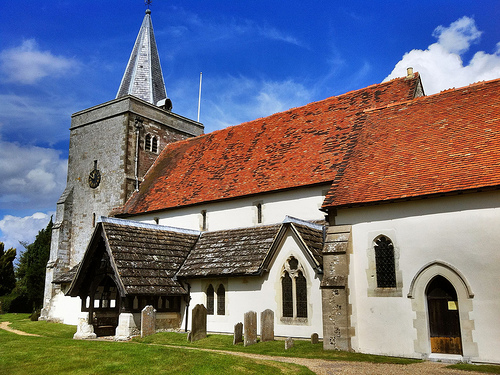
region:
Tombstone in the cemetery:
[138, 303, 158, 342]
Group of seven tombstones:
[140, 300, 324, 356]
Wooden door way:
[411, 260, 463, 359]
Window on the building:
[365, 230, 401, 297]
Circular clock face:
[84, 161, 106, 195]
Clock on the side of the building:
[85, 163, 103, 190]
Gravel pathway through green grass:
[0, 305, 480, 374]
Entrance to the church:
[82, 255, 126, 343]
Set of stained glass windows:
[277, 251, 310, 326]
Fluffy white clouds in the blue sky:
[348, 4, 498, 102]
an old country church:
[40, 5, 497, 374]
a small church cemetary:
[133, 290, 325, 353]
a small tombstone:
[308, 332, 318, 346]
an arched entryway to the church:
[411, 257, 481, 362]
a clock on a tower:
[84, 163, 105, 191]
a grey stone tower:
[62, 106, 213, 315]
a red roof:
[113, 67, 498, 215]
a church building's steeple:
[112, 7, 177, 119]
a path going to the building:
[1, 317, 485, 374]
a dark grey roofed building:
[48, 212, 333, 352]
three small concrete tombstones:
[230, 298, 275, 349]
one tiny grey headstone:
[279, 335, 305, 353]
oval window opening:
[355, 225, 407, 302]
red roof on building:
[312, 90, 498, 197]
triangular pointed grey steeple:
[100, 0, 175, 110]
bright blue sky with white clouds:
[295, 3, 465, 79]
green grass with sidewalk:
[90, 340, 197, 370]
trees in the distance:
[0, 227, 36, 307]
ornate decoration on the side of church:
[82, 157, 104, 192]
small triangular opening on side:
[67, 212, 139, 340]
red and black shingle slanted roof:
[126, 74, 416, 218]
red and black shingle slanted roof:
[328, 81, 497, 198]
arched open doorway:
[423, 269, 465, 357]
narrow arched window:
[372, 232, 394, 293]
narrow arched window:
[281, 253, 306, 322]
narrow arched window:
[216, 279, 228, 314]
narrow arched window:
[206, 284, 214, 319]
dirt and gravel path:
[1, 315, 436, 373]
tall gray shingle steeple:
[113, 7, 168, 107]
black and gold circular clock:
[88, 169, 102, 186]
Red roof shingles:
[176, 121, 395, 219]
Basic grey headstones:
[122, 284, 318, 359]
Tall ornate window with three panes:
[270, 247, 330, 333]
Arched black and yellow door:
[406, 253, 482, 361]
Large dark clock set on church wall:
[72, 160, 109, 198]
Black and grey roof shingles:
[185, 225, 311, 283]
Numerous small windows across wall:
[142, 205, 341, 229]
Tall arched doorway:
[71, 226, 171, 342]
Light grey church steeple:
[87, 0, 206, 126]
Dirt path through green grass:
[0, 284, 77, 356]